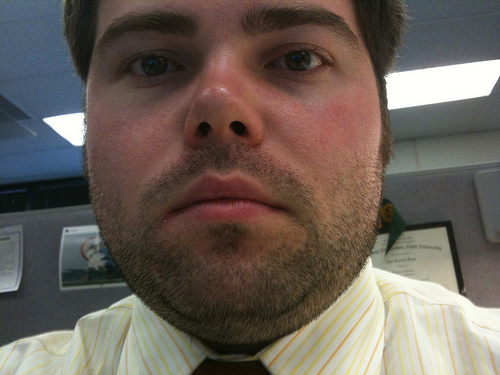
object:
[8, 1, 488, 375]
man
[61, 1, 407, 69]
hair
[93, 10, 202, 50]
eyebrow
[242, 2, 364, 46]
eyebrow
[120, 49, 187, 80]
eye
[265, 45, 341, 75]
eye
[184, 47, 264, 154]
nose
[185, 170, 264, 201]
lips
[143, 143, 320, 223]
mustache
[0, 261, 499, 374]
shirt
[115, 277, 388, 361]
lapel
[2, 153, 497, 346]
wall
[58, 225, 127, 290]
picture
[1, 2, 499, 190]
ceiling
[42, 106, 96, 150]
light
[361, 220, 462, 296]
certificate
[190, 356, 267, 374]
tie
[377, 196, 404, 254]
pennant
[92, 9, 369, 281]
face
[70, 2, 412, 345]
head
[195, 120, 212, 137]
nostril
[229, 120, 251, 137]
nostril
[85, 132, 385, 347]
facial hair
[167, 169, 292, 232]
mouth